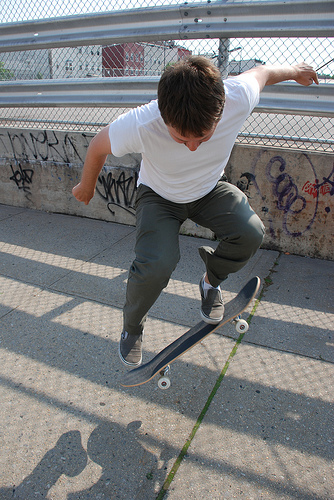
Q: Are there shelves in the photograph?
A: No, there are no shelves.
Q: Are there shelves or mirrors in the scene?
A: No, there are no shelves or mirrors.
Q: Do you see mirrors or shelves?
A: No, there are no shelves or mirrors.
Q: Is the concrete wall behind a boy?
A: Yes, the wall is behind a boy.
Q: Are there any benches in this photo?
A: No, there are no benches.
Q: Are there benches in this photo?
A: No, there are no benches.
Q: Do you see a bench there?
A: No, there are no benches.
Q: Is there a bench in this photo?
A: No, there are no benches.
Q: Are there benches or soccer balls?
A: No, there are no benches or soccer balls.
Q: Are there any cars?
A: No, there are no cars.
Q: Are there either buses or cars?
A: No, there are no cars or buses.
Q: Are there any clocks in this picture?
A: No, there are no clocks.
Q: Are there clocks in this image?
A: No, there are no clocks.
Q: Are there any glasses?
A: No, there are no glasses.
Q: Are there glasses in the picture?
A: No, there are no glasses.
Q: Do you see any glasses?
A: No, there are no glasses.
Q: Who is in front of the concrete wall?
A: The boy is in front of the wall.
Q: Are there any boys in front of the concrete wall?
A: Yes, there is a boy in front of the wall.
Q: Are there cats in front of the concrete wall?
A: No, there is a boy in front of the wall.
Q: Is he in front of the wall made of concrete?
A: Yes, the boy is in front of the wall.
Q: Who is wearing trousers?
A: The boy is wearing trousers.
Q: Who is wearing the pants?
A: The boy is wearing trousers.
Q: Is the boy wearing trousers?
A: Yes, the boy is wearing trousers.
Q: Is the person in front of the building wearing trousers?
A: Yes, the boy is wearing trousers.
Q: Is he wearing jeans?
A: No, the boy is wearing trousers.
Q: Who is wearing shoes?
A: The boy is wearing shoes.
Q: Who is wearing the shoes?
A: The boy is wearing shoes.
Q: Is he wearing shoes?
A: Yes, the boy is wearing shoes.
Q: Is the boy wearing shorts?
A: No, the boy is wearing shoes.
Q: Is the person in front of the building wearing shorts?
A: No, the boy is wearing shoes.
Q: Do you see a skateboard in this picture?
A: Yes, there is a skateboard.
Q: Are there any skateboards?
A: Yes, there is a skateboard.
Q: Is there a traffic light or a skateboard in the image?
A: Yes, there is a skateboard.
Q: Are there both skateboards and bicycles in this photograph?
A: No, there is a skateboard but no bicycles.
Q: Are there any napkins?
A: No, there are no napkins.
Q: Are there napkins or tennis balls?
A: No, there are no napkins or tennis balls.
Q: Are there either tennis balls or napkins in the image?
A: No, there are no napkins or tennis balls.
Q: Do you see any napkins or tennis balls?
A: No, there are no napkins or tennis balls.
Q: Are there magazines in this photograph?
A: No, there are no magazines.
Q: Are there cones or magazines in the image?
A: No, there are no magazines or cones.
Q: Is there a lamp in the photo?
A: No, there are no lamps.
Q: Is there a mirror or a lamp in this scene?
A: No, there are no lamps or mirrors.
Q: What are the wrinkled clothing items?
A: The clothing items are pants.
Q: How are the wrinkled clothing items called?
A: The clothing items are pants.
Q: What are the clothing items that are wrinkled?
A: The clothing items are pants.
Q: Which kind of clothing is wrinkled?
A: The clothing is pants.